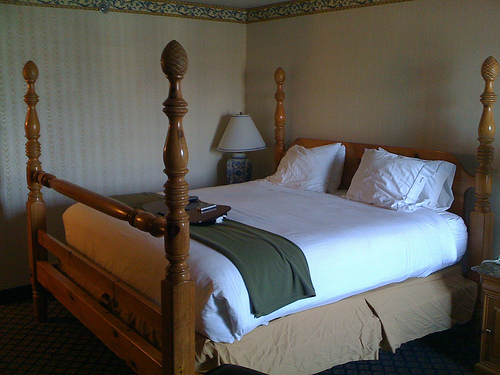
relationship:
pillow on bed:
[265, 138, 472, 208] [64, 208, 424, 314]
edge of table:
[469, 258, 488, 367] [473, 258, 499, 372]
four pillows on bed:
[290, 148, 454, 210] [21, 50, 498, 344]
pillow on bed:
[265, 138, 342, 192] [21, 35, 499, 374]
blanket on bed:
[112, 185, 320, 322] [21, 35, 499, 374]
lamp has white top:
[212, 107, 272, 188] [211, 109, 270, 155]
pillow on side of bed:
[342, 146, 433, 213] [72, 141, 463, 346]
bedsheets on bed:
[60, 264, 481, 374] [21, 35, 499, 374]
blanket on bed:
[112, 185, 317, 318] [21, 35, 499, 374]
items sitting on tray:
[166, 189, 220, 219] [145, 186, 225, 227]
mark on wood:
[103, 293, 120, 313] [16, 31, 497, 370]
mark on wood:
[63, 289, 75, 304] [16, 31, 497, 370]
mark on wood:
[168, 220, 179, 238] [16, 31, 497, 370]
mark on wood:
[58, 245, 78, 256] [16, 31, 497, 370]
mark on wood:
[127, 355, 137, 369] [16, 31, 497, 370]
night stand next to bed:
[468, 255, 498, 372] [332, 138, 426, 208]